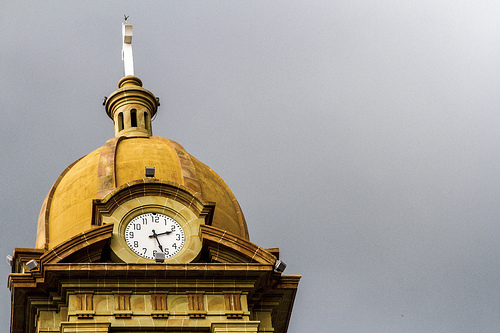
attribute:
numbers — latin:
[94, 217, 221, 257]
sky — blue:
[300, 133, 359, 163]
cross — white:
[93, 43, 201, 83]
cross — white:
[82, 27, 206, 96]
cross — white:
[92, 47, 212, 103]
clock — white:
[123, 178, 208, 311]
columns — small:
[80, 262, 201, 331]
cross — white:
[101, 62, 202, 101]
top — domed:
[76, 112, 198, 235]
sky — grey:
[283, 138, 443, 278]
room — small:
[90, 76, 207, 184]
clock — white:
[142, 203, 169, 249]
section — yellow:
[32, 171, 108, 211]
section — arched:
[40, 177, 155, 311]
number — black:
[122, 216, 155, 232]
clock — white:
[152, 170, 217, 276]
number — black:
[158, 213, 196, 272]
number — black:
[142, 220, 194, 250]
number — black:
[162, 228, 202, 274]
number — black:
[169, 240, 192, 245]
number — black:
[159, 227, 180, 241]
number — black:
[129, 217, 172, 263]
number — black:
[91, 247, 170, 257]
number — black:
[144, 238, 164, 274]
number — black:
[102, 225, 211, 286]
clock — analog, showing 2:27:
[123, 209, 185, 261]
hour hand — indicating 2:
[148, 227, 172, 238]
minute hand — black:
[150, 225, 165, 254]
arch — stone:
[23, 225, 280, 274]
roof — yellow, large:
[6, 76, 301, 332]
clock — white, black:
[125, 213, 185, 257]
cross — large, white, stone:
[118, 22, 138, 72]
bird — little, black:
[121, 12, 131, 20]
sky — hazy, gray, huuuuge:
[0, 1, 499, 331]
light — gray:
[20, 255, 40, 276]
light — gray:
[272, 259, 286, 274]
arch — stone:
[91, 178, 216, 227]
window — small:
[114, 112, 126, 131]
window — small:
[128, 107, 140, 129]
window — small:
[143, 110, 153, 130]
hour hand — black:
[148, 228, 174, 238]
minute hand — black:
[150, 231, 164, 254]